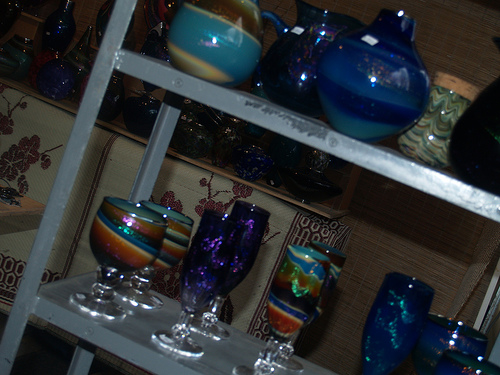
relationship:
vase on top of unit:
[309, 5, 432, 147] [1, 1, 498, 375]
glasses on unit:
[147, 205, 249, 366] [1, 1, 498, 375]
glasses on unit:
[194, 196, 272, 348] [1, 1, 498, 375]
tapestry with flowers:
[1, 88, 352, 372] [1, 134, 67, 208]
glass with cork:
[397, 84, 475, 174] [429, 68, 482, 105]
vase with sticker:
[309, 5, 432, 147] [358, 32, 378, 50]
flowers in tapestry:
[1, 134, 67, 208] [1, 88, 352, 372]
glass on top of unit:
[397, 84, 475, 174] [1, 1, 498, 375]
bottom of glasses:
[147, 325, 208, 362] [147, 205, 249, 366]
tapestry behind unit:
[1, 88, 352, 372] [1, 1, 498, 375]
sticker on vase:
[358, 32, 378, 50] [309, 5, 432, 147]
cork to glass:
[429, 68, 482, 105] [397, 84, 475, 174]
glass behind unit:
[34, 59, 76, 103] [1, 1, 498, 375]